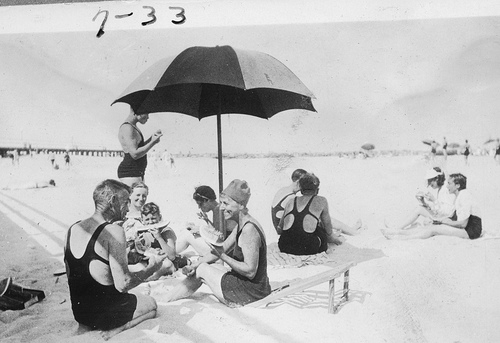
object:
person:
[116, 104, 164, 187]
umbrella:
[108, 43, 319, 237]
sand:
[0, 154, 499, 342]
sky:
[0, 0, 500, 148]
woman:
[121, 180, 149, 266]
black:
[10, 287, 28, 302]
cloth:
[0, 277, 45, 312]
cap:
[219, 179, 250, 207]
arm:
[121, 127, 153, 160]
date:
[88, 6, 195, 39]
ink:
[91, 7, 197, 41]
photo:
[0, 0, 499, 343]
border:
[0, 0, 499, 37]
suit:
[221, 218, 273, 306]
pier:
[3, 143, 129, 157]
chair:
[243, 262, 356, 314]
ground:
[0, 154, 500, 338]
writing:
[90, 4, 186, 39]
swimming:
[159, 148, 497, 163]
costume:
[116, 119, 147, 182]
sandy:
[0, 154, 499, 342]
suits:
[63, 219, 139, 332]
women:
[277, 171, 347, 254]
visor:
[426, 167, 445, 181]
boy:
[133, 201, 178, 262]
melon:
[134, 220, 170, 233]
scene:
[0, 0, 498, 340]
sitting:
[380, 172, 487, 243]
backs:
[66, 218, 118, 311]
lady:
[164, 179, 270, 309]